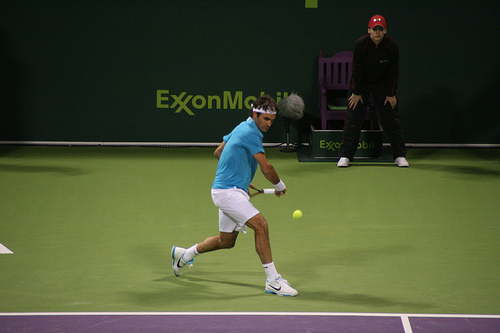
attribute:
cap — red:
[366, 14, 388, 31]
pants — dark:
[340, 84, 407, 156]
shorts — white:
[212, 185, 263, 233]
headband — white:
[249, 102, 275, 114]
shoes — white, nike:
[167, 244, 297, 299]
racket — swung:
[249, 183, 275, 199]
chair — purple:
[315, 48, 375, 128]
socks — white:
[262, 261, 279, 282]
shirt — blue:
[213, 117, 267, 191]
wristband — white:
[274, 178, 289, 195]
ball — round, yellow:
[292, 206, 305, 221]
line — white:
[1, 309, 500, 323]